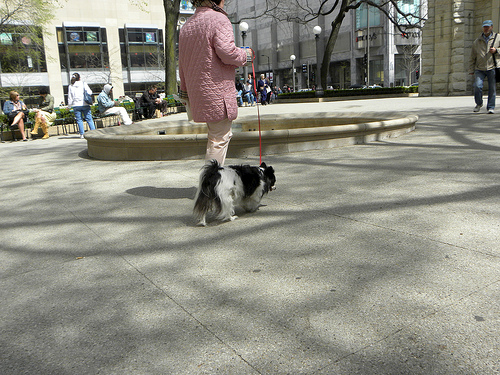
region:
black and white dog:
[194, 155, 282, 222]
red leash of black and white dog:
[244, 47, 271, 168]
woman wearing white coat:
[63, 73, 100, 135]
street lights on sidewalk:
[235, 16, 335, 100]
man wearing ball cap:
[465, 17, 497, 117]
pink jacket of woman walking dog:
[173, 10, 253, 127]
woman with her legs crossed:
[5, 92, 35, 145]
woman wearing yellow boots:
[26, 91, 60, 143]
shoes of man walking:
[471, 102, 498, 119]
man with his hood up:
[93, 81, 133, 126]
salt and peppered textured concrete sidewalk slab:
[40, 292, 172, 369]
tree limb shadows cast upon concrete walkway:
[425, 121, 497, 209]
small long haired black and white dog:
[188, 157, 281, 229]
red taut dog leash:
[248, 46, 268, 163]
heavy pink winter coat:
[174, 8, 250, 120]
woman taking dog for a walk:
[175, 0, 279, 231]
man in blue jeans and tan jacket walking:
[461, 13, 496, 115]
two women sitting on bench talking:
[3, 88, 60, 148]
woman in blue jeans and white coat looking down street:
[66, 68, 98, 146]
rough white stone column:
[448, 4, 468, 93]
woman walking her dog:
[162, 0, 319, 264]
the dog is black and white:
[177, 149, 289, 231]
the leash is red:
[240, 47, 274, 184]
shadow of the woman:
[107, 160, 204, 207]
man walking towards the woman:
[460, 16, 498, 120]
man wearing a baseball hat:
[469, 7, 496, 47]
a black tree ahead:
[293, 0, 403, 111]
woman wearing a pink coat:
[144, 12, 259, 133]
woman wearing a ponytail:
[61, 66, 87, 92]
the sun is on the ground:
[376, 193, 496, 310]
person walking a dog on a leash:
[166, 1, 291, 228]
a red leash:
[240, 55, 278, 165]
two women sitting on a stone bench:
[2, 80, 58, 140]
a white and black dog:
[177, 158, 287, 225]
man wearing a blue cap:
[475, 12, 495, 32]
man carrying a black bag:
[485, 32, 495, 87]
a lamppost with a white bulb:
[297, 23, 327, 90]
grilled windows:
[57, 22, 108, 73]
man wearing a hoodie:
[95, 80, 120, 115]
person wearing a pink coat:
[172, 10, 253, 124]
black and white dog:
[191, 159, 279, 231]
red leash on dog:
[244, 49, 281, 203]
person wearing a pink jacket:
[171, 5, 258, 125]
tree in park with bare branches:
[285, 5, 371, 100]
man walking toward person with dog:
[470, 10, 498, 114]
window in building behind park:
[50, 8, 117, 73]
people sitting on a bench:
[3, 88, 70, 155]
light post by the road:
[281, 51, 301, 91]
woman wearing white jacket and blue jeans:
[63, 68, 100, 136]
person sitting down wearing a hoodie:
[94, 83, 123, 118]